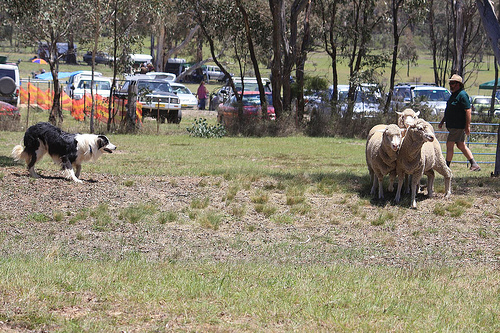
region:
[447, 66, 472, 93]
Person wearing hat on head.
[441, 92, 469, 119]
Person wearing green shirt.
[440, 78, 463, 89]
Sunglasses on person's face.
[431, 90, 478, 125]
Person wearing green shirt.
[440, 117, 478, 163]
Person wearing khaki shorts.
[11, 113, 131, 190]
Black and white dog standing in grassy area.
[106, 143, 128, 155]
Dog has black nose.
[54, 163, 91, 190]
Dog has white paw.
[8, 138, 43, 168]
Dog has white tail.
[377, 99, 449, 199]
3 white sheep standing in grass.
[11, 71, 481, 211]
dog watching over sheep and man watching over dog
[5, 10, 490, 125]
cars parked behind tree and fence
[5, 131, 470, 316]
bare ground between light green grass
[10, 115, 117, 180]
large black and white dog standing at attention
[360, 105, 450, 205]
tan sheep clustered close together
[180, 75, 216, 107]
woman walking between parked cars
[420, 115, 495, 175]
blue metal fence behind man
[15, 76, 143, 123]
orange and yellow fabric across fence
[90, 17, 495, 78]
large grassy area behind cars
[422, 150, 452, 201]
legs out to side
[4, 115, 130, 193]
Dog is black and white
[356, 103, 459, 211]
Three sheep huddled together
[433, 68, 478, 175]
Man is walking in the grass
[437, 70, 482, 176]
Man is wearing brown hat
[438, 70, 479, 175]
Man is wearing green shirt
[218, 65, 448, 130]
Cars in a parking lot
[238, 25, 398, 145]
Trees by the parking lot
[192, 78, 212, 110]
Person standing beside car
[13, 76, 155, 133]
Red and yellow caution fence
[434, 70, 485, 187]
Men wearing khaki shorts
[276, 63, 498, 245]
flock of sheep standing together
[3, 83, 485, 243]
dog facing flock of sheep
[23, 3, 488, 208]
multiple cars parked in background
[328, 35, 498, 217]
man walking behind sheep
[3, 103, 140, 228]
dog is black and white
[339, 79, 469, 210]
sheep in flock are tan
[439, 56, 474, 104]
man wearing tan hat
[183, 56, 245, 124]
person standing near car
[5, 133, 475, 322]
brown patch of grass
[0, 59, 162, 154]
orange mesh on fence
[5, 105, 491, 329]
green grassy field with a dog and three sheep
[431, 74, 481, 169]
man with shorts and a dark short sleeve shirt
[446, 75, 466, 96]
man walking and wearing a tan hat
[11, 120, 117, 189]
black and white sheep dog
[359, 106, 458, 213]
three sheep standing in a grassy field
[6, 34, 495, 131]
many parked cars near a grassy field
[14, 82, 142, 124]
orange fencing near a grassy area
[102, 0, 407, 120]
trees near a green grassy area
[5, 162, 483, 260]
sparsely grassed area with mostly dirt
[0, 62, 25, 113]
black and white back of an SUV